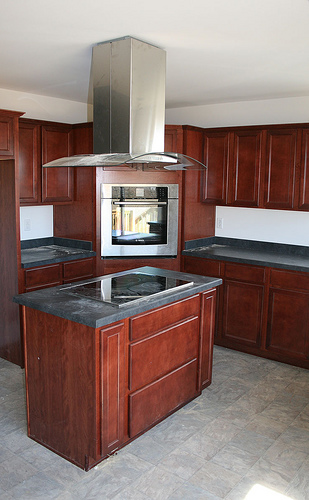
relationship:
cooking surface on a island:
[56, 270, 193, 306] [11, 264, 221, 473]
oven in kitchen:
[101, 180, 180, 255] [8, 93, 296, 421]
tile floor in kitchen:
[0, 337, 309, 499] [6, 133, 291, 465]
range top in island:
[76, 270, 191, 305] [11, 264, 221, 473]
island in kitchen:
[11, 264, 221, 473] [6, 133, 291, 465]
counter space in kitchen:
[186, 238, 298, 263] [6, 133, 291, 465]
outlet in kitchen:
[215, 216, 225, 228] [8, 93, 296, 421]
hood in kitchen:
[41, 35, 206, 174] [5, 71, 296, 401]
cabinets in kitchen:
[12, 122, 298, 204] [8, 93, 296, 421]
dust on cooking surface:
[26, 289, 110, 319] [13, 260, 225, 321]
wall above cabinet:
[4, 86, 307, 128] [0, 109, 308, 212]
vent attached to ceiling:
[45, 36, 209, 169] [1, 0, 308, 114]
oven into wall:
[101, 180, 180, 255] [2, 88, 307, 266]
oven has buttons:
[101, 180, 180, 255] [114, 187, 131, 197]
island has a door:
[30, 264, 221, 453] [100, 326, 127, 445]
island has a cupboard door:
[11, 264, 221, 473] [200, 291, 214, 387]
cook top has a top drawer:
[81, 276, 165, 310] [137, 308, 192, 327]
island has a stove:
[11, 264, 221, 473] [93, 269, 173, 306]